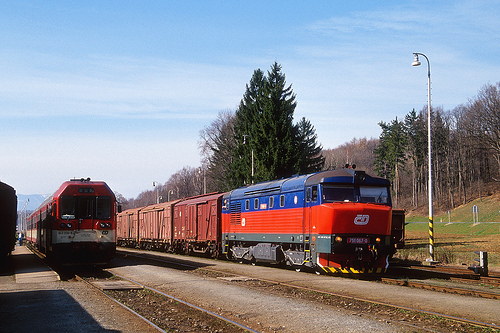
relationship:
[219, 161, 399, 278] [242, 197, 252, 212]
engine has window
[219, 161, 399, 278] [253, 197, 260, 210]
engine has window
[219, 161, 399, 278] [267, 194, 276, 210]
engine has window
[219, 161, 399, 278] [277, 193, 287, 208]
engine has window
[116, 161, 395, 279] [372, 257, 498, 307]
train parked on track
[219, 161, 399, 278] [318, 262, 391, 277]
engine has yellow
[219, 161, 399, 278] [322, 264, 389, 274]
engine has black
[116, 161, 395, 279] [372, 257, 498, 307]
train on track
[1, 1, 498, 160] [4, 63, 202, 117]
sky has cloud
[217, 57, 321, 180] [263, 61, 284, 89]
tree has top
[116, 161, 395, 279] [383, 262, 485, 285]
train has shadow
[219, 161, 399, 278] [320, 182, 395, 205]
engine has window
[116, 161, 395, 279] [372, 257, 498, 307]
train sitting on track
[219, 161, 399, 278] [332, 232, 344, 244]
engine has light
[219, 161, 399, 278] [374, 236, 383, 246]
engine has light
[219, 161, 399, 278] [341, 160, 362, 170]
engine has horn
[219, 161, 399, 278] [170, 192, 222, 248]
engine pulling car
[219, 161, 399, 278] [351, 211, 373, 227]
engine has logo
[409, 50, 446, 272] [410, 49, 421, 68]
pole has light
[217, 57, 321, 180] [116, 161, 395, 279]
tree behind train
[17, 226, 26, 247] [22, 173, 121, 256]
man standing by train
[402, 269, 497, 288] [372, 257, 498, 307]
ballast beside track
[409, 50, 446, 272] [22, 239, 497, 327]
pole by a track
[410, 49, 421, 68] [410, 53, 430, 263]
light on side